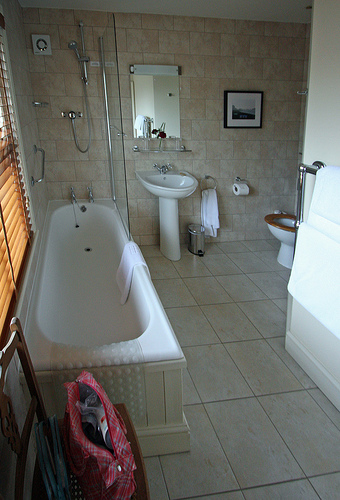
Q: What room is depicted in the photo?
A: A bathroom.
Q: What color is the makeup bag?
A: Red.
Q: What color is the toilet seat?
A: Brown.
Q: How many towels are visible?
A: Four.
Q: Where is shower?
A: In the left hand corner.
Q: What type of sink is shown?
A: Pedestal.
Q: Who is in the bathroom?
A: No one.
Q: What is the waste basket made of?
A: Metal.